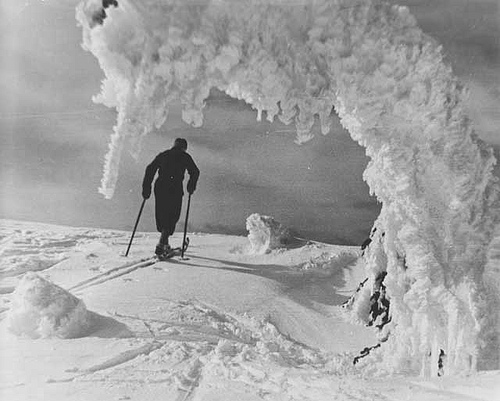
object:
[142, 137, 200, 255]
man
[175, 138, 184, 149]
dark hair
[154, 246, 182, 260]
skis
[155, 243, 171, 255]
man's feet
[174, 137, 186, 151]
head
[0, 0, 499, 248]
sky